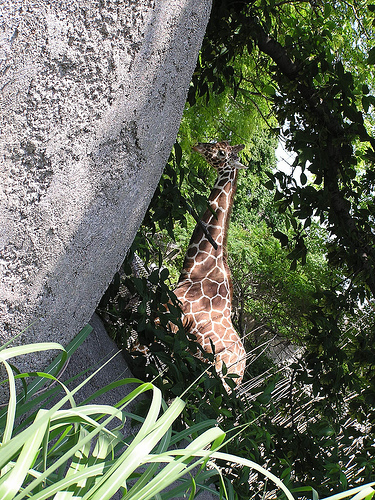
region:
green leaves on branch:
[209, 6, 371, 265]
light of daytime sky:
[271, 14, 371, 198]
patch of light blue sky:
[272, 128, 309, 189]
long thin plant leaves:
[3, 339, 283, 499]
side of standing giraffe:
[175, 140, 246, 389]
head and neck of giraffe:
[183, 142, 248, 300]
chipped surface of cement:
[0, 0, 210, 350]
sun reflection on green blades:
[5, 381, 233, 498]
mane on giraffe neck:
[194, 167, 239, 308]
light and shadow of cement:
[1, 0, 213, 336]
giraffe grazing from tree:
[186, 135, 245, 396]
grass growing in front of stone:
[0, 336, 242, 497]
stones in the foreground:
[3, 2, 192, 441]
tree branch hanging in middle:
[226, 4, 361, 261]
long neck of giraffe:
[178, 175, 238, 263]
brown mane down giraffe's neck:
[225, 172, 245, 286]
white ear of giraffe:
[230, 159, 245, 175]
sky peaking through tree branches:
[269, 118, 321, 208]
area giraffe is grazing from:
[164, 21, 235, 229]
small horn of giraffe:
[232, 141, 244, 153]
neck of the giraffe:
[187, 183, 253, 246]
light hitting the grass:
[86, 414, 199, 482]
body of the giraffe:
[174, 258, 283, 361]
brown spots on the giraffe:
[182, 281, 242, 339]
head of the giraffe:
[191, 137, 261, 179]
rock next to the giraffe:
[67, 73, 189, 175]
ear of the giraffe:
[230, 151, 254, 175]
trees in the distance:
[249, 216, 333, 304]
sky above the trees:
[273, 145, 300, 175]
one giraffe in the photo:
[135, 121, 326, 355]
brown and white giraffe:
[128, 140, 245, 387]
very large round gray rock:
[0, 1, 213, 417]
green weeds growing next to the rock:
[96, 257, 345, 496]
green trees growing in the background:
[160, 2, 373, 332]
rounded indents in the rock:
[86, 118, 144, 187]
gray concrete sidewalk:
[0, 312, 225, 496]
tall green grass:
[1, 324, 364, 498]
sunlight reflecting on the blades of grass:
[4, 337, 369, 498]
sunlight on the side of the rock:
[0, 0, 178, 346]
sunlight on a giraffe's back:
[129, 141, 246, 396]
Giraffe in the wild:
[165, 140, 245, 394]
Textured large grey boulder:
[1, 0, 214, 414]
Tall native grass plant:
[0, 317, 374, 498]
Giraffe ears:
[226, 143, 250, 171]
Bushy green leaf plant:
[96, 0, 374, 499]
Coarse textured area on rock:
[86, 121, 148, 205]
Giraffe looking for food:
[134, 137, 246, 397]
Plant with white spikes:
[213, 306, 373, 497]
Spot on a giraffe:
[199, 277, 219, 300]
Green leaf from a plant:
[298, 173, 308, 188]